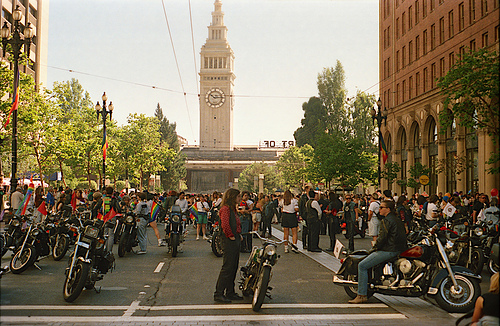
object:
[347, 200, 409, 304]
man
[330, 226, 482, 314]
motorbike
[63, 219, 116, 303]
motorbikes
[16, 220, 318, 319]
road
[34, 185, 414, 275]
crowd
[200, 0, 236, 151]
clock tower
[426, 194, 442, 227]
people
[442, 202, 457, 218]
flags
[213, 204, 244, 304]
woman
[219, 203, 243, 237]
shirt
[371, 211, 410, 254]
jacket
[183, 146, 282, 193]
building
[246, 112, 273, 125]
background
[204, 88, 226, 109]
clock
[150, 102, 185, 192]
trees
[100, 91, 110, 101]
street lights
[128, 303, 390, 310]
lines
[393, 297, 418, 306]
bricks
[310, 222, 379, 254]
sidewalk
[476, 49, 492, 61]
leaves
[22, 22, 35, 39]
lights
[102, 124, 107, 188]
poles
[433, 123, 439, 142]
windows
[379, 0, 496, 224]
building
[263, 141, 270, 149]
letters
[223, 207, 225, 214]
red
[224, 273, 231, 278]
black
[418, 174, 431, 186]
sign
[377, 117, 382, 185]
light pole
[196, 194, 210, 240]
person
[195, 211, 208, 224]
shorts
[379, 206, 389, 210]
sunglasses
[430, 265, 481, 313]
wheel